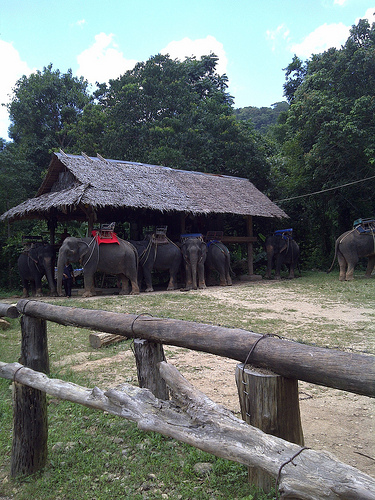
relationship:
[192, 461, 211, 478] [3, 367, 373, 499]
rock in grass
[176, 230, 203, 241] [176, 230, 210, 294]
seats on elephant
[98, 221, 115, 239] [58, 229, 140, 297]
seat on elephant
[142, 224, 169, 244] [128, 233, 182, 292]
elephant seat on elephant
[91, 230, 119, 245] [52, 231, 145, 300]
blanket on elephant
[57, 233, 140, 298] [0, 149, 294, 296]
elephant standing under barn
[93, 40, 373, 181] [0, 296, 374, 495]
tree used as fence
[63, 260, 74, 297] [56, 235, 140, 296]
person standing beside elephant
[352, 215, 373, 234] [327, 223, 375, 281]
seats on elephant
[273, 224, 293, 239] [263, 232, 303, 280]
seats on elephants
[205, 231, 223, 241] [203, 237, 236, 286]
bench on elephants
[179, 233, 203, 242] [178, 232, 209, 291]
seats on elephants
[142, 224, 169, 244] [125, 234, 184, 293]
elephant seat on elephants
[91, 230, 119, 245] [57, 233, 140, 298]
blanket on elephant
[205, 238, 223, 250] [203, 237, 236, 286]
blankets on elephants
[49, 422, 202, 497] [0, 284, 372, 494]
pebbles on ground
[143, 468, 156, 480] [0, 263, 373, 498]
pebble on ground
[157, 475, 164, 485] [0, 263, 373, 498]
pebble on ground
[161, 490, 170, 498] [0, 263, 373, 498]
pebble on ground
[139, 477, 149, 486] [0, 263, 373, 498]
pebble on ground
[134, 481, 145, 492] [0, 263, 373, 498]
pebble on ground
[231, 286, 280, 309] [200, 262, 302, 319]
pebbles on ground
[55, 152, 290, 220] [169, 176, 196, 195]
roof made of hay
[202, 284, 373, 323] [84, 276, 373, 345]
dirt in grass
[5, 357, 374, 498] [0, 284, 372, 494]
log on ground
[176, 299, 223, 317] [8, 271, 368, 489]
patch of grass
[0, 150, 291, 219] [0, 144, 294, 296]
roof of barn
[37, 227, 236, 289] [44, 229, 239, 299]
herd of elephants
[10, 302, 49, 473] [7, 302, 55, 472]
post used for a post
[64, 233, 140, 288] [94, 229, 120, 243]
elephant with a seat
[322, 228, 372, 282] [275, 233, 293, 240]
elephant with blanket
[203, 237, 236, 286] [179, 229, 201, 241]
elephant with blue seat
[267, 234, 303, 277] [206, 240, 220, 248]
elephant with blankets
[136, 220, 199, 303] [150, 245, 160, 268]
elephant with straps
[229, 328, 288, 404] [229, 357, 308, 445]
wire on post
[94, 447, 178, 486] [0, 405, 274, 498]
rocks in grass